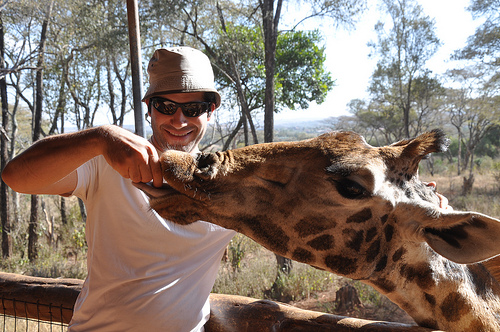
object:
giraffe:
[130, 124, 499, 330]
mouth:
[130, 152, 213, 210]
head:
[130, 127, 499, 281]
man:
[2, 45, 239, 331]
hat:
[140, 47, 224, 111]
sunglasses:
[146, 93, 214, 118]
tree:
[200, 21, 334, 149]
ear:
[392, 199, 499, 267]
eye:
[325, 167, 377, 209]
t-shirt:
[59, 138, 240, 331]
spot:
[292, 213, 339, 240]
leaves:
[306, 80, 320, 89]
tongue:
[129, 176, 178, 201]